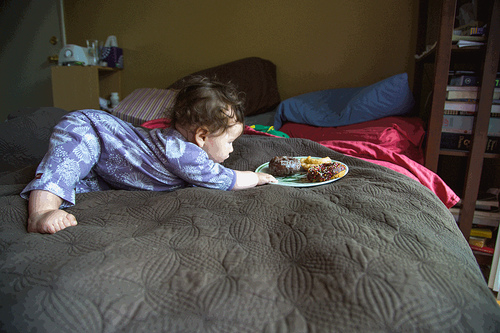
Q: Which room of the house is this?
A: It is a bedroom.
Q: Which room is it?
A: It is a bedroom.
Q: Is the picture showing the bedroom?
A: Yes, it is showing the bedroom.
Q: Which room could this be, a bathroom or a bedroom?
A: It is a bedroom.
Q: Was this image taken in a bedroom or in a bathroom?
A: It was taken at a bedroom.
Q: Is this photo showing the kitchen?
A: No, the picture is showing the bedroom.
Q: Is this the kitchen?
A: No, it is the bedroom.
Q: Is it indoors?
A: Yes, it is indoors.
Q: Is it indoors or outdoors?
A: It is indoors.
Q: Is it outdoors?
A: No, it is indoors.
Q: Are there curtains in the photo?
A: No, there are no curtains.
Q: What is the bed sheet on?
A: The bed sheet is on the bed.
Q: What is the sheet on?
A: The bed sheet is on the bed.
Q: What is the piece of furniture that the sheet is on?
A: The piece of furniture is a bed.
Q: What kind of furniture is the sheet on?
A: The sheet is on the bed.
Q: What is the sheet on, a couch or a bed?
A: The sheet is on a bed.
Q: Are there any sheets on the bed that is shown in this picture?
A: Yes, there is a sheet on the bed.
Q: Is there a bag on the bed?
A: No, there is a sheet on the bed.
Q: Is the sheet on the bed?
A: Yes, the sheet is on the bed.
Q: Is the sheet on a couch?
A: No, the sheet is on the bed.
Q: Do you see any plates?
A: Yes, there is a plate.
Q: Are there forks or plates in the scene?
A: Yes, there is a plate.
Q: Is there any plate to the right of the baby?
A: Yes, there is a plate to the right of the baby.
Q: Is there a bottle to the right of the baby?
A: No, there is a plate to the right of the baby.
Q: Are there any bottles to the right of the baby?
A: No, there is a plate to the right of the baby.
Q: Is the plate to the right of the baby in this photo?
A: Yes, the plate is to the right of the baby.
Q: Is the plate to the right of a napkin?
A: No, the plate is to the right of the baby.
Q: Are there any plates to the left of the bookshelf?
A: Yes, there is a plate to the left of the bookshelf.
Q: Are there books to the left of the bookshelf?
A: No, there is a plate to the left of the bookshelf.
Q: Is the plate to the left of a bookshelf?
A: Yes, the plate is to the left of a bookshelf.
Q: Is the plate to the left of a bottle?
A: No, the plate is to the left of a bookshelf.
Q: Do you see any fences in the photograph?
A: No, there are no fences.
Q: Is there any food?
A: Yes, there is food.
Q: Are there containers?
A: No, there are no containers.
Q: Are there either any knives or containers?
A: No, there are no containers or knives.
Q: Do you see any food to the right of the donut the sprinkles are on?
A: Yes, there is food to the right of the donut.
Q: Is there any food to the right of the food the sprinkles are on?
A: Yes, there is food to the right of the donut.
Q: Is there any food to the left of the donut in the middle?
A: No, the food is to the right of the donut.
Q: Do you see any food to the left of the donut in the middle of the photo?
A: No, the food is to the right of the donut.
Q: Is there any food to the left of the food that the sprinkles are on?
A: No, the food is to the right of the donut.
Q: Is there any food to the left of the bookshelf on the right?
A: Yes, there is food to the left of the bookshelf.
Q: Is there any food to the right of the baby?
A: Yes, there is food to the right of the baby.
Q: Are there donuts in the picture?
A: Yes, there is a donut.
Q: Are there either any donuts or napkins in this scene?
A: Yes, there is a donut.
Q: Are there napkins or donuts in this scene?
A: Yes, there is a donut.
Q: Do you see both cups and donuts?
A: No, there is a donut but no cups.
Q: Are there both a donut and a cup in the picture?
A: No, there is a donut but no cups.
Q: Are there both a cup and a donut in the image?
A: No, there is a donut but no cups.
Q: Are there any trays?
A: No, there are no trays.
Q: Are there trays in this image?
A: No, there are no trays.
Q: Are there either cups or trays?
A: No, there are no trays or cups.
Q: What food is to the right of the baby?
A: The food is a donut.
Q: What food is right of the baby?
A: The food is a donut.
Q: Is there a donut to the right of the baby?
A: Yes, there is a donut to the right of the baby.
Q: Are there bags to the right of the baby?
A: No, there is a donut to the right of the baby.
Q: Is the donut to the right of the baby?
A: Yes, the donut is to the right of the baby.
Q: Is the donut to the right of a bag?
A: No, the donut is to the right of the baby.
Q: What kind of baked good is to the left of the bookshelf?
A: The food is a donut.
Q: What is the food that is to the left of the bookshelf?
A: The food is a donut.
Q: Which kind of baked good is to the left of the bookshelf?
A: The food is a donut.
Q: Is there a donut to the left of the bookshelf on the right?
A: Yes, there is a donut to the left of the bookshelf.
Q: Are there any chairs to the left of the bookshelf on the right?
A: No, there is a donut to the left of the bookshelf.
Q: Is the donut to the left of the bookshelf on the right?
A: Yes, the donut is to the left of the bookshelf.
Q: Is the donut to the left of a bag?
A: No, the donut is to the left of the bookshelf.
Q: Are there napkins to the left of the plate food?
A: No, there is a donut to the left of the food.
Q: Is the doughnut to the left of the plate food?
A: Yes, the doughnut is to the left of the food.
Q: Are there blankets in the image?
A: Yes, there is a blanket.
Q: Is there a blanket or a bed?
A: Yes, there is a blanket.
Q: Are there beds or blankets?
A: Yes, there is a blanket.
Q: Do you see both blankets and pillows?
A: Yes, there are both a blanket and a pillow.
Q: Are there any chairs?
A: No, there are no chairs.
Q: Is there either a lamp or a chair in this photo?
A: No, there are no chairs or lamps.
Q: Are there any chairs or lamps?
A: No, there are no chairs or lamps.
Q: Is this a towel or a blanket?
A: This is a blanket.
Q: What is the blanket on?
A: The blanket is on the bed.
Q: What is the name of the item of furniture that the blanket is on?
A: The piece of furniture is a bed.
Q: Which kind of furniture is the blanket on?
A: The blanket is on the bed.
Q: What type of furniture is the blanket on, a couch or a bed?
A: The blanket is on a bed.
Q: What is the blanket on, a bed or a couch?
A: The blanket is on a bed.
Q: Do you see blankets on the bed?
A: Yes, there is a blanket on the bed.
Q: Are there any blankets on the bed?
A: Yes, there is a blanket on the bed.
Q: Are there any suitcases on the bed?
A: No, there is a blanket on the bed.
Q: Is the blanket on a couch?
A: No, the blanket is on a bed.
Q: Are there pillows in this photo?
A: Yes, there is a pillow.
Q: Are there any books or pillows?
A: Yes, there is a pillow.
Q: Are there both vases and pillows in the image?
A: No, there is a pillow but no vases.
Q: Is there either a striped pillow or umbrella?
A: Yes, there is a striped pillow.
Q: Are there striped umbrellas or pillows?
A: Yes, there is a striped pillow.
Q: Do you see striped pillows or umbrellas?
A: Yes, there is a striped pillow.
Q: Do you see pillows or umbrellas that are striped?
A: Yes, the pillow is striped.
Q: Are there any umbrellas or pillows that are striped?
A: Yes, the pillow is striped.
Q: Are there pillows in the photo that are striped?
A: Yes, there is a striped pillow.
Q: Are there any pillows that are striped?
A: Yes, there is a pillow that is striped.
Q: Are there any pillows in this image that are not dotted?
A: Yes, there is a striped pillow.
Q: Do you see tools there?
A: No, there are no tools.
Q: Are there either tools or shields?
A: No, there are no tools or shields.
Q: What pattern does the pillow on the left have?
A: The pillow has striped pattern.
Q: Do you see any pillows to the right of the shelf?
A: Yes, there is a pillow to the right of the shelf.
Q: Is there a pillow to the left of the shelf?
A: No, the pillow is to the right of the shelf.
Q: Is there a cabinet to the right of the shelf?
A: No, there is a pillow to the right of the shelf.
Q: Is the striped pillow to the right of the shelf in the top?
A: Yes, the pillow is to the right of the shelf.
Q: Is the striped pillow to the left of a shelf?
A: No, the pillow is to the right of a shelf.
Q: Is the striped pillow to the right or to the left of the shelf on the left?
A: The pillow is to the right of the shelf.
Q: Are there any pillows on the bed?
A: Yes, there is a pillow on the bed.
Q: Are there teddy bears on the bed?
A: No, there is a pillow on the bed.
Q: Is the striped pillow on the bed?
A: Yes, the pillow is on the bed.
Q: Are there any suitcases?
A: No, there are no suitcases.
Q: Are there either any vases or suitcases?
A: No, there are no suitcases or vases.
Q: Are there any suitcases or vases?
A: No, there are no suitcases or vases.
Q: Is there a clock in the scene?
A: No, there are no clocks.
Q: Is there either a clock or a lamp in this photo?
A: No, there are no clocks or lamps.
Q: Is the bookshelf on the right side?
A: Yes, the bookshelf is on the right of the image.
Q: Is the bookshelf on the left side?
A: No, the bookshelf is on the right of the image.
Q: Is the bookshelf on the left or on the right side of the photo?
A: The bookshelf is on the right of the image.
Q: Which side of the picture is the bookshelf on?
A: The bookshelf is on the right of the image.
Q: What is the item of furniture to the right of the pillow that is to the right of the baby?
A: The piece of furniture is a bookshelf.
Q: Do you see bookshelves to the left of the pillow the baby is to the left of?
A: No, the bookshelf is to the right of the pillow.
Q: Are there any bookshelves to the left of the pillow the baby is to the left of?
A: No, the bookshelf is to the right of the pillow.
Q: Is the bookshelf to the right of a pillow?
A: Yes, the bookshelf is to the right of a pillow.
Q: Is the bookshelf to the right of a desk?
A: No, the bookshelf is to the right of a pillow.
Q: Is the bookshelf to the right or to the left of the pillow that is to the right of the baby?
A: The bookshelf is to the right of the pillow.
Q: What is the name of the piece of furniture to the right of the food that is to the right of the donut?
A: The piece of furniture is a bookshelf.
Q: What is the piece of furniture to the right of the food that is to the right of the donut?
A: The piece of furniture is a bookshelf.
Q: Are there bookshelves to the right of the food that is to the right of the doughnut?
A: Yes, there is a bookshelf to the right of the food.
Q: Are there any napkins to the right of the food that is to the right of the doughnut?
A: No, there is a bookshelf to the right of the food.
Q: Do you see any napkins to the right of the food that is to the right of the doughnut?
A: No, there is a bookshelf to the right of the food.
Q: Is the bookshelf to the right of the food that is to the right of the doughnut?
A: Yes, the bookshelf is to the right of the food.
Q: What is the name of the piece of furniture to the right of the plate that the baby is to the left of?
A: The piece of furniture is a bookshelf.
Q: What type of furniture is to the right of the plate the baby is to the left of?
A: The piece of furniture is a bookshelf.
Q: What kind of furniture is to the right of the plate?
A: The piece of furniture is a bookshelf.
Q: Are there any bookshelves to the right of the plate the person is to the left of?
A: Yes, there is a bookshelf to the right of the plate.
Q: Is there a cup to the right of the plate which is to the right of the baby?
A: No, there is a bookshelf to the right of the plate.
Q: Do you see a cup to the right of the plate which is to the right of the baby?
A: No, there is a bookshelf to the right of the plate.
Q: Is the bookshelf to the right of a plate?
A: Yes, the bookshelf is to the right of a plate.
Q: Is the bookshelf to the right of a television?
A: No, the bookshelf is to the right of a plate.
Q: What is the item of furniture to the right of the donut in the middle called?
A: The piece of furniture is a bookshelf.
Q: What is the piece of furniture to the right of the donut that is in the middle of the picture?
A: The piece of furniture is a bookshelf.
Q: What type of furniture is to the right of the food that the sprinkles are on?
A: The piece of furniture is a bookshelf.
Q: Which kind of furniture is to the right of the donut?
A: The piece of furniture is a bookshelf.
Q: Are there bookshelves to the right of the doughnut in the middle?
A: Yes, there is a bookshelf to the right of the donut.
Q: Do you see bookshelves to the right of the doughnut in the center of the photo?
A: Yes, there is a bookshelf to the right of the donut.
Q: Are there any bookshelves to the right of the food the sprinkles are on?
A: Yes, there is a bookshelf to the right of the donut.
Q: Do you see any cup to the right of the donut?
A: No, there is a bookshelf to the right of the donut.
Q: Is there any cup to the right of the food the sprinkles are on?
A: No, there is a bookshelf to the right of the donut.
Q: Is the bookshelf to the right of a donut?
A: Yes, the bookshelf is to the right of a donut.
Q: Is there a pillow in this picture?
A: Yes, there is a pillow.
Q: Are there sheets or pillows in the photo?
A: Yes, there is a pillow.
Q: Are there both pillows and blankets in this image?
A: Yes, there are both a pillow and a blanket.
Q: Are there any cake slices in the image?
A: No, there are no cake slices.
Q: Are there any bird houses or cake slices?
A: No, there are no cake slices or bird houses.